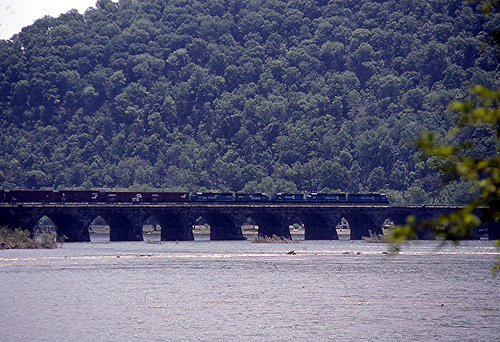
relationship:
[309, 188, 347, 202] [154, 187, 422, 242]
car on tracks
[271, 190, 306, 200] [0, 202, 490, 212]
train car on tracks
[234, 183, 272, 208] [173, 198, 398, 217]
train car on tracks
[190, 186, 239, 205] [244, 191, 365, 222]
car on tracks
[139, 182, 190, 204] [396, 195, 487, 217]
car on tracks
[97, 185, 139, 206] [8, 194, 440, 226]
car on tracks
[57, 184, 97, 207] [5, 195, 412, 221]
train car on tracks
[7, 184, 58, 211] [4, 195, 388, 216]
car on tracks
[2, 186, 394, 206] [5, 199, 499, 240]
train crossing bridge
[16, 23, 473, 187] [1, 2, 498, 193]
trees covering hill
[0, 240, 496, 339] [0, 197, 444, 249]
water next to bridge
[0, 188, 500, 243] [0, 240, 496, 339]
bridge over water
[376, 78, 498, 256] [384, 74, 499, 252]
leaves attached to branches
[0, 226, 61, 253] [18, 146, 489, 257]
grass beside bridge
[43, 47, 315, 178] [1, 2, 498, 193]
trees in hill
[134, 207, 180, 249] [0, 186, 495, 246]
arch on bridge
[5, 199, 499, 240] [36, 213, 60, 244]
bridge has arch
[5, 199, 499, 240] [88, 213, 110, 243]
bridge has arch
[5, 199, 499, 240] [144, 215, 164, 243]
bridge has arch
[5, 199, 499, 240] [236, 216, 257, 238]
bridge has arch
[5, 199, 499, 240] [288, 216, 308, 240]
bridge has arch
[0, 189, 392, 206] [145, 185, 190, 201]
train has car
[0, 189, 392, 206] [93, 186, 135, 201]
train has car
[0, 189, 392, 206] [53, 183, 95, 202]
train has car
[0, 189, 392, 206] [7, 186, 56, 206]
train has car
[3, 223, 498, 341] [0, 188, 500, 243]
water under bridge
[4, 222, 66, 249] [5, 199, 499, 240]
bushes beside bridge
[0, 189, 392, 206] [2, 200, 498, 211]
train on tracks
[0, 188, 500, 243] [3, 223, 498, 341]
bridge over water